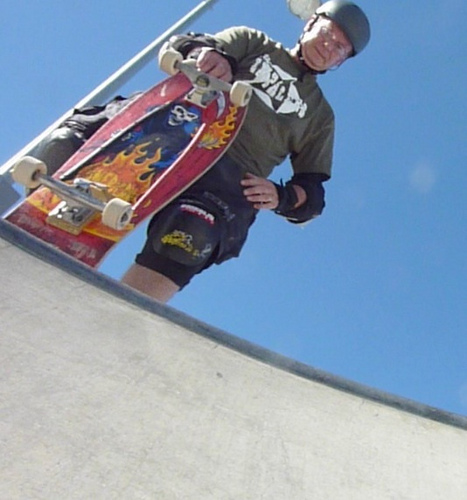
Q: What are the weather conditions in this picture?
A: It is clear.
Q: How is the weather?
A: It is clear.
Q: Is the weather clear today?
A: Yes, it is clear.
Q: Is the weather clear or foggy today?
A: It is clear.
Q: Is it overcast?
A: No, it is clear.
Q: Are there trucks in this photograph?
A: Yes, there are trucks.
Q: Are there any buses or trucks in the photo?
A: Yes, there are trucks.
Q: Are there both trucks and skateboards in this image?
A: Yes, there are both trucks and a skateboard.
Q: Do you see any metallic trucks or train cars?
A: Yes, there are metal trucks.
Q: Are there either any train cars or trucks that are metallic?
A: Yes, the trucks are metallic.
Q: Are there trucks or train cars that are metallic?
A: Yes, the trucks are metallic.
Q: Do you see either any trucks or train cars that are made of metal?
A: Yes, the trucks are made of metal.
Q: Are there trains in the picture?
A: No, there are no trains.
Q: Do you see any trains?
A: No, there are no trains.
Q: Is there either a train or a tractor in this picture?
A: No, there are no trains or tractors.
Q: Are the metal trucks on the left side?
A: Yes, the trucks are on the left of the image.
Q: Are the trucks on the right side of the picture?
A: No, the trucks are on the left of the image.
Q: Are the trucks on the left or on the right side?
A: The trucks are on the left of the image.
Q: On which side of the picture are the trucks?
A: The trucks are on the left of the image.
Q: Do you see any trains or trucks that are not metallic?
A: No, there are trucks but they are metallic.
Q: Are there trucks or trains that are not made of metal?
A: No, there are trucks but they are made of metal.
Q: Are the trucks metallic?
A: Yes, the trucks are metallic.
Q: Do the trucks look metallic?
A: Yes, the trucks are metallic.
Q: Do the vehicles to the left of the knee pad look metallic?
A: Yes, the trucks are metallic.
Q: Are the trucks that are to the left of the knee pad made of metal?
A: Yes, the trucks are made of metal.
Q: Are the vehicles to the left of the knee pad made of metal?
A: Yes, the trucks are made of metal.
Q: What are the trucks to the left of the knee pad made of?
A: The trucks are made of metal.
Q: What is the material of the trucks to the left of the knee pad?
A: The trucks are made of metal.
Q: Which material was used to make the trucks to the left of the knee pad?
A: The trucks are made of metal.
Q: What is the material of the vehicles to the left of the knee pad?
A: The trucks are made of metal.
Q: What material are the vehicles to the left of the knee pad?
A: The trucks are made of metal.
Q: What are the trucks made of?
A: The trucks are made of metal.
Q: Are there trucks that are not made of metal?
A: No, there are trucks but they are made of metal.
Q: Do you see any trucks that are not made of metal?
A: No, there are trucks but they are made of metal.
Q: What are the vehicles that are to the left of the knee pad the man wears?
A: The vehicles are trucks.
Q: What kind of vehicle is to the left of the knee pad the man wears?
A: The vehicles are trucks.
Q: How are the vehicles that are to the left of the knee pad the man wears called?
A: The vehicles are trucks.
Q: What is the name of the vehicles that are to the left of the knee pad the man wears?
A: The vehicles are trucks.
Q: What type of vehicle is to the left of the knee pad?
A: The vehicles are trucks.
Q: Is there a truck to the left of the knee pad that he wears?
A: Yes, there are trucks to the left of the knee pad.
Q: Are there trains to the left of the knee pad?
A: No, there are trucks to the left of the knee pad.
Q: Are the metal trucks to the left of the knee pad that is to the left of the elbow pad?
A: Yes, the trucks are to the left of the knee pad.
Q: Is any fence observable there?
A: No, there are no fences.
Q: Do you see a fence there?
A: No, there are no fences.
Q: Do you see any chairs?
A: No, there are no chairs.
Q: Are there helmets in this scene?
A: Yes, there is a helmet.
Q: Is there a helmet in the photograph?
A: Yes, there is a helmet.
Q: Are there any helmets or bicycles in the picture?
A: Yes, there is a helmet.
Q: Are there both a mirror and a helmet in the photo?
A: No, there is a helmet but no mirrors.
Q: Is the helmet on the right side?
A: Yes, the helmet is on the right of the image.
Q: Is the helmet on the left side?
A: No, the helmet is on the right of the image.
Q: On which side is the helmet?
A: The helmet is on the right of the image.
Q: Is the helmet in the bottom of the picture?
A: No, the helmet is in the top of the image.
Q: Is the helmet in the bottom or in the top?
A: The helmet is in the top of the image.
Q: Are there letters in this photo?
A: Yes, there are letters.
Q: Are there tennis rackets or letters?
A: Yes, there are letters.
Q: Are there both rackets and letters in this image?
A: No, there are letters but no rackets.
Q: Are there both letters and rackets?
A: No, there are letters but no rackets.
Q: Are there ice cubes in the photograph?
A: No, there are no ice cubes.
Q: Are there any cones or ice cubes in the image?
A: No, there are no ice cubes or cones.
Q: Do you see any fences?
A: No, there are no fences.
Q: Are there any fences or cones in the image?
A: No, there are no fences or cones.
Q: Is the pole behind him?
A: Yes, the pole is behind the man.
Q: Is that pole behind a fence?
A: No, the pole is behind the man.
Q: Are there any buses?
A: No, there are no buses.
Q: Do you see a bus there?
A: No, there are no buses.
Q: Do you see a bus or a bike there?
A: No, there are no buses or bikes.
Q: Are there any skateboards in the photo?
A: Yes, there is a skateboard.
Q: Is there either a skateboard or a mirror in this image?
A: Yes, there is a skateboard.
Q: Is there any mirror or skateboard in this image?
A: Yes, there is a skateboard.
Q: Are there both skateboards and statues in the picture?
A: No, there is a skateboard but no statues.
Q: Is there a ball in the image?
A: No, there are no balls.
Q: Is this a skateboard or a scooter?
A: This is a skateboard.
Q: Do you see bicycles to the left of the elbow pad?
A: No, there is a skateboard to the left of the elbow pad.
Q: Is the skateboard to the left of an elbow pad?
A: Yes, the skateboard is to the left of an elbow pad.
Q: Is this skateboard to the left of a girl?
A: No, the skateboard is to the left of an elbow pad.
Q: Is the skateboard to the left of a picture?
A: Yes, the skateboard is to the left of a picture.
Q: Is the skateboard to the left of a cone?
A: No, the skateboard is to the left of a picture.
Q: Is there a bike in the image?
A: No, there are no bikes.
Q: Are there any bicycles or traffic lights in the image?
A: No, there are no bicycles or traffic lights.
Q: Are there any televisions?
A: No, there are no televisions.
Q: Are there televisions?
A: No, there are no televisions.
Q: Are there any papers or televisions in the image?
A: No, there are no televisions or papers.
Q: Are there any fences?
A: No, there are no fences.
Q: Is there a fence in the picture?
A: No, there are no fences.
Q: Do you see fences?
A: No, there are no fences.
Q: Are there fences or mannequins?
A: No, there are no fences or mannequins.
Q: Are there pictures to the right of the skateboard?
A: Yes, there is a picture to the right of the skateboard.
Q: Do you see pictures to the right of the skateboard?
A: Yes, there is a picture to the right of the skateboard.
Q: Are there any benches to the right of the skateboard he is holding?
A: No, there is a picture to the right of the skateboard.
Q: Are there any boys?
A: No, there are no boys.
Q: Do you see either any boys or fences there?
A: No, there are no boys or fences.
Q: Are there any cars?
A: No, there are no cars.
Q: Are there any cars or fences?
A: No, there are no cars or fences.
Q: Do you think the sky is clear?
A: Yes, the sky is clear.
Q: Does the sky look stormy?
A: No, the sky is clear.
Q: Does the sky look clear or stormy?
A: The sky is clear.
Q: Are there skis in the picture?
A: No, there are no skis.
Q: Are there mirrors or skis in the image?
A: No, there are no skis or mirrors.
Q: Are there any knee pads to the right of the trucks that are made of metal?
A: Yes, there is a knee pad to the right of the trucks.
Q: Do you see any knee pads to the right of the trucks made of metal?
A: Yes, there is a knee pad to the right of the trucks.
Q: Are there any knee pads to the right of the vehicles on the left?
A: Yes, there is a knee pad to the right of the trucks.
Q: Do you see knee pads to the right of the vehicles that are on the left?
A: Yes, there is a knee pad to the right of the trucks.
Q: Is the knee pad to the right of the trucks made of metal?
A: Yes, the knee pad is to the right of the trucks.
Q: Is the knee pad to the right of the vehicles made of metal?
A: Yes, the knee pad is to the right of the trucks.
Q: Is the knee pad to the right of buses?
A: No, the knee pad is to the right of the trucks.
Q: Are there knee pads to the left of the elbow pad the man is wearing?
A: Yes, there is a knee pad to the left of the elbow pad.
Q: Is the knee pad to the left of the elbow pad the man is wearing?
A: Yes, the knee pad is to the left of the elbow pad.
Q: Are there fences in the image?
A: No, there are no fences.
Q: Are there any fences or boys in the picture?
A: No, there are no fences or boys.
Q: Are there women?
A: No, there are no women.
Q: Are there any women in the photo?
A: No, there are no women.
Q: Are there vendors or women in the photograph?
A: No, there are no women or vendors.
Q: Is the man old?
A: Yes, the man is old.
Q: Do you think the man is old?
A: Yes, the man is old.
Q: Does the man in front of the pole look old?
A: Yes, the man is old.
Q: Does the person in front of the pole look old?
A: Yes, the man is old.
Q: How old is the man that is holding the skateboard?
A: The man is old.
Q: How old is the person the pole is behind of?
A: The man is old.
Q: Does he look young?
A: No, the man is old.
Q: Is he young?
A: No, the man is old.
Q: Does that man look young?
A: No, the man is old.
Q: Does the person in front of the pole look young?
A: No, the man is old.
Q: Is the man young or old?
A: The man is old.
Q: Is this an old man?
A: Yes, this is an old man.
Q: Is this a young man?
A: No, this is an old man.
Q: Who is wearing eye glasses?
A: The man is wearing eye glasses.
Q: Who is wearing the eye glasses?
A: The man is wearing eye glasses.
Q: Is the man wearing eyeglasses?
A: Yes, the man is wearing eyeglasses.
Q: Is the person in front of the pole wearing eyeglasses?
A: Yes, the man is wearing eyeglasses.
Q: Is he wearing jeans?
A: No, the man is wearing eyeglasses.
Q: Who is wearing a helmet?
A: The man is wearing a helmet.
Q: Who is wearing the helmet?
A: The man is wearing a helmet.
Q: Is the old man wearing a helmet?
A: Yes, the man is wearing a helmet.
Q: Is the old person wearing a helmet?
A: Yes, the man is wearing a helmet.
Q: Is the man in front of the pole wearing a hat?
A: No, the man is wearing a helmet.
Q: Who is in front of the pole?
A: The man is in front of the pole.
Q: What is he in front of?
A: The man is in front of the pole.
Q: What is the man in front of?
A: The man is in front of the pole.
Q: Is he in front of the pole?
A: Yes, the man is in front of the pole.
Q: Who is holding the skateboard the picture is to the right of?
A: The man is holding the skateboard.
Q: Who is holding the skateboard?
A: The man is holding the skateboard.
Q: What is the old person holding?
A: The man is holding the skateboard.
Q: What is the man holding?
A: The man is holding the skateboard.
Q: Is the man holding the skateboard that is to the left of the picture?
A: Yes, the man is holding the skateboard.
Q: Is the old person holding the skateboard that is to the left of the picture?
A: Yes, the man is holding the skateboard.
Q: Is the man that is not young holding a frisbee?
A: No, the man is holding the skateboard.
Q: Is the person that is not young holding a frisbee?
A: No, the man is holding the skateboard.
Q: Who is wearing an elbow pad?
A: The man is wearing an elbow pad.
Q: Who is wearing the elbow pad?
A: The man is wearing an elbow pad.